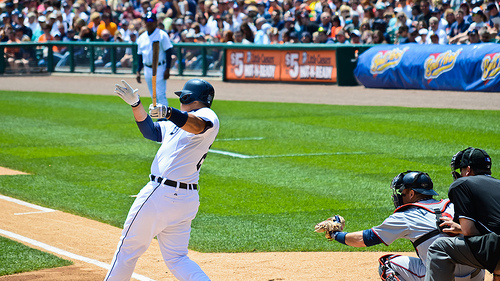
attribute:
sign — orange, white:
[226, 39, 346, 98]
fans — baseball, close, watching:
[226, 4, 478, 40]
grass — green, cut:
[254, 112, 358, 186]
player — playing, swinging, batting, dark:
[112, 69, 223, 247]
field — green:
[19, 123, 325, 274]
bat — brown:
[133, 36, 172, 114]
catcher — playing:
[366, 151, 439, 253]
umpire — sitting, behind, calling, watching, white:
[455, 142, 500, 249]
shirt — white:
[156, 132, 207, 197]